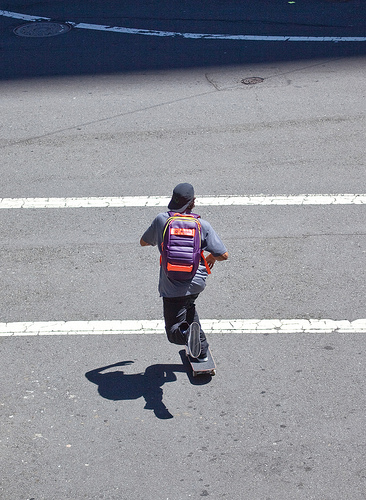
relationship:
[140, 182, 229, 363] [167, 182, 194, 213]
boy wearing cap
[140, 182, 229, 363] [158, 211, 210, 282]
boy wearing backpack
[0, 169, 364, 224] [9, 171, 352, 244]
line on street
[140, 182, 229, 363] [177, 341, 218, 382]
boy riding skateboard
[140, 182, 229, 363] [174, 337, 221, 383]
boy riding skateboard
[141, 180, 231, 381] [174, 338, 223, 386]
boy riding skateboard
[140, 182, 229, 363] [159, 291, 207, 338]
boy wearing pants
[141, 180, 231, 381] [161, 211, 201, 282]
boy wearing backpack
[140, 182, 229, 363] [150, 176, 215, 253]
boy wearing cap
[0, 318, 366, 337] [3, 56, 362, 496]
lines in street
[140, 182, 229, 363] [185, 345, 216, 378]
boy riding skateboard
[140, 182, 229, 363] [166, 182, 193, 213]
boy wearing hat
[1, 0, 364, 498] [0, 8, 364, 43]
asphalt has lines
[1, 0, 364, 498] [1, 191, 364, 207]
asphalt has lines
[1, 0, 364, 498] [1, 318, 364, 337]
asphalt has lines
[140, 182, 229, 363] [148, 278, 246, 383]
boy riding skateboard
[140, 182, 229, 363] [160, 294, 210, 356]
boy wearing dark pants